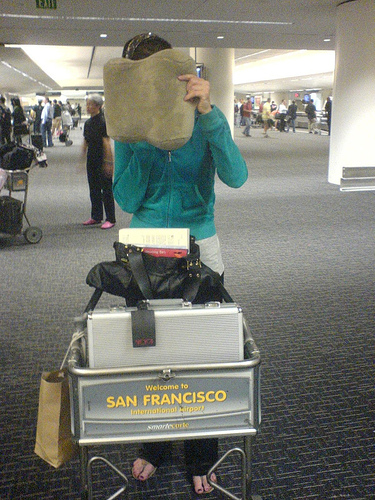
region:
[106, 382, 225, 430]
yellow text on the cart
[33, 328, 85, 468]
brown bag hanging from the cart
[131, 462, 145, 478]
woman's toes are painted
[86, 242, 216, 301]
black leather purse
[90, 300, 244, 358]
large metal carry case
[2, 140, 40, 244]
the luggage cart is full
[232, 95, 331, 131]
people waiting by the baggage return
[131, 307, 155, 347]
black ID tag on the case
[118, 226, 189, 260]
a white book in the purse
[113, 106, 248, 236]
a front zip up sweater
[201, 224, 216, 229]
blue fabric on shirt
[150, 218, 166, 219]
blue fabric on shirt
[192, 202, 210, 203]
blue fabric on shirt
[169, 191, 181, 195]
blue fabric on shirt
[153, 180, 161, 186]
blue fabric on shirt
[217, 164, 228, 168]
blue fabric on shirt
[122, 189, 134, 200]
blue fabric on shirt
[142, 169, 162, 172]
blue fabric on shirt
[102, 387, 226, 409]
San Francisco on a cart.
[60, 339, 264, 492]
The cart is grey.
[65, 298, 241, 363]
Briefcase in the cart.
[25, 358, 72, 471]
Bag on the cart.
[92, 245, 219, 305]
Handbag on the cart.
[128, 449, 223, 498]
The woman is wearing sandals.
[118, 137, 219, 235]
The jacket is teal.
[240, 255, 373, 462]
The floor is carpeted.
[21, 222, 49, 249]
Wheels on the cart.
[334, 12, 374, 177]
The wall is white.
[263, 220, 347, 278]
light on the floor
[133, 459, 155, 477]
the womens foot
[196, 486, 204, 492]
toenail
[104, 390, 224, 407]
letters are yellow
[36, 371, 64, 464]
a brown paper bag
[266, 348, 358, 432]
the carpet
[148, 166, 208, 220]
the women is wearing a green sweater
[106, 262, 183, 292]
a black purse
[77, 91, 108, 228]
a person standing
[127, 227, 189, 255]
books in the black purse